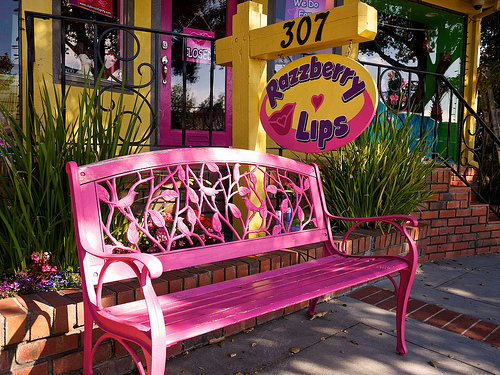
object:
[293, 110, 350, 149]
alphabet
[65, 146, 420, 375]
bench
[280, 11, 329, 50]
number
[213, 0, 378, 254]
post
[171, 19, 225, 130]
window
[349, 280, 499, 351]
brick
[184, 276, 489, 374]
sidewalk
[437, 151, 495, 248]
steps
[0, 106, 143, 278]
grass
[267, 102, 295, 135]
lips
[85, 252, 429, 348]
bench seat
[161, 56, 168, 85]
handle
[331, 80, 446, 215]
plants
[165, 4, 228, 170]
door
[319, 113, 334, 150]
letter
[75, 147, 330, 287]
back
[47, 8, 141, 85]
window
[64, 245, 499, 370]
ground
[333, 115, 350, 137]
letter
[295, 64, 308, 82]
letter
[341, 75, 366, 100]
letter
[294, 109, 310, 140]
letter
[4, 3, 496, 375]
building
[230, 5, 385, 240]
sign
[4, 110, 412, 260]
garden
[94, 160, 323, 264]
pattern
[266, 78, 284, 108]
alphabet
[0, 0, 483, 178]
business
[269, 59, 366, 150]
razzberry lips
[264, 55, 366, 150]
alphabet